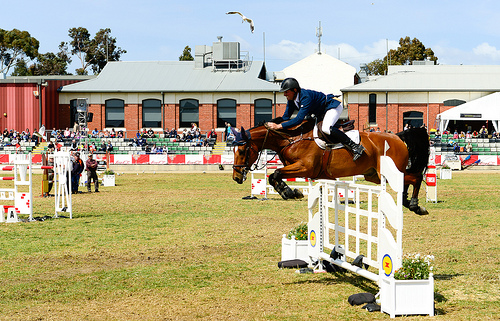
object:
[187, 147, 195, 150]
seating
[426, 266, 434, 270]
flowers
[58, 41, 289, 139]
building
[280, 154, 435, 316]
fence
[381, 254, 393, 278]
logo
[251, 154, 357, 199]
fence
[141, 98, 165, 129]
window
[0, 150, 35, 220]
fence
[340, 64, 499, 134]
building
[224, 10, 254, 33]
seabird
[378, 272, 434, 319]
planter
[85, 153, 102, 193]
person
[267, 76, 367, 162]
person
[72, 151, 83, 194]
person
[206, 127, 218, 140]
person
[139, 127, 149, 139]
person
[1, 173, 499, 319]
field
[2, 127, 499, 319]
arena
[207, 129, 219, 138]
spectators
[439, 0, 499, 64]
air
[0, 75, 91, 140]
building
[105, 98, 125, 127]
window